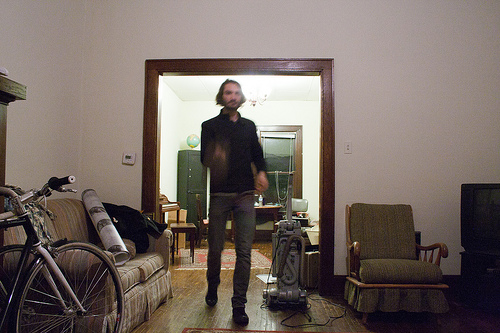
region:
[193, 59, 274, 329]
man walking in the living room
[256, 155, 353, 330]
vacuum sitting on the floor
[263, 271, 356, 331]
black cord on the floor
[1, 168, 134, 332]
bike in the living room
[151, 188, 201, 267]
brown piano bench by a piano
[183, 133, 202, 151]
globe sitting on a piece of furniture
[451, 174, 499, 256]
television in the corner of the room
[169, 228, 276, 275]
rug on the floor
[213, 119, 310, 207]
window on the wall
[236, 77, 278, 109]
light fixture on the ceiling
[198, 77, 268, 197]
one man wearing dark sweater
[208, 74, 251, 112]
one man with straight dark hair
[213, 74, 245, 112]
one man with dark beard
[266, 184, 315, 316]
one gray upright vacuum cleaner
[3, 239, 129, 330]
one round front bicycle tire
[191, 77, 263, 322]
one man wearing light denim pants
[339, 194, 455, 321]
one green patterned chair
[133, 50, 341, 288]
man standing in dark wood trimmed doorway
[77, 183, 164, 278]
one rolled white and black poster on couch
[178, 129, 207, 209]
one globe on top of green wooden cabinet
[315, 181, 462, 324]
a green and brown armchair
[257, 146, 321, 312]
a large gray vacuum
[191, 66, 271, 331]
a tall man walking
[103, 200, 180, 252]
a jacket on the arm of a sofa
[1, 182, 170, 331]
an old greenish sofa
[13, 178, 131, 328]
the front of a bicycle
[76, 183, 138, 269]
a rolled up poster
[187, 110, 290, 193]
a man's black shirt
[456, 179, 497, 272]
the edge of a TV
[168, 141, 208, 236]
a green cabinet in a kitchen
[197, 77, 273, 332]
guy walking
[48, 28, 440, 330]
guy in a room walking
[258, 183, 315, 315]
a vacuum in the room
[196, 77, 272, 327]
a person wearing jeans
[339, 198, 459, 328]
gliding chair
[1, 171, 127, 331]
bicycle in the room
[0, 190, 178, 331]
a couch in the room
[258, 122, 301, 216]
a window in the room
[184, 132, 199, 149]
a glove on top of the cabinet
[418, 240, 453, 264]
an armrest on chair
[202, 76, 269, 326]
Man walking into room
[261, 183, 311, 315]
Vacuum cleaner to right of man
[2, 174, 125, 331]
Bicycle next to the sofa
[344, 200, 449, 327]
Chair to the right of the doorway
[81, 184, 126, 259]
Large papers rolled up on sofa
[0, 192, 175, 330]
Sofa on left wall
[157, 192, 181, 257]
Keyboard in next room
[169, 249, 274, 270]
Rug on the wood floor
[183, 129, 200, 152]
Globe on top of the cabinet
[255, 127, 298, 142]
Rolled up blind on the window